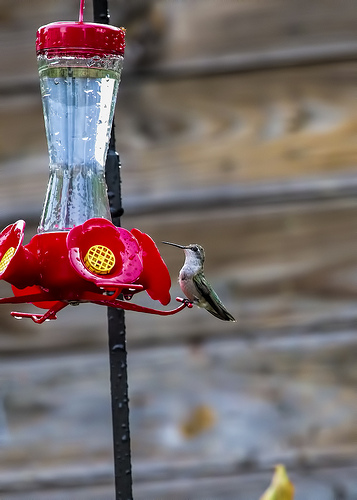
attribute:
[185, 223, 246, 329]
bird — standing, hummingbird, brown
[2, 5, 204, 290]
feeder — hanging, red, flower, clear, glass, yellow, wet, in foreground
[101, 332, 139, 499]
pole — black, wet, long, thin, metal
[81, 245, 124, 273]
middle — yellow, plastic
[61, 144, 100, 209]
water — drops, droplets, drop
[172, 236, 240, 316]
hummingbird — female, ruby-throated, small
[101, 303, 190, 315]
perch — red, little, plastic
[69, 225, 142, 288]
shape — flower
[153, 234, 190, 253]
beak — long, black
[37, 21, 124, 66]
cap — red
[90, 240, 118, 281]
screen — yellow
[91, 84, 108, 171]
reflection — light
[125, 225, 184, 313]
feeding station — flower shaped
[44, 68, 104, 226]
middle — clear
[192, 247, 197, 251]
eye — small, black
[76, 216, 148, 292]
flower — red, plastic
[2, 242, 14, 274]
food dispenser — mesh, yellow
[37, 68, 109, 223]
tank — clear, water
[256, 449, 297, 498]
bird — yellow, blurry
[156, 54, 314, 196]
wall — blurry, wooden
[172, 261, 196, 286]
feathers — white